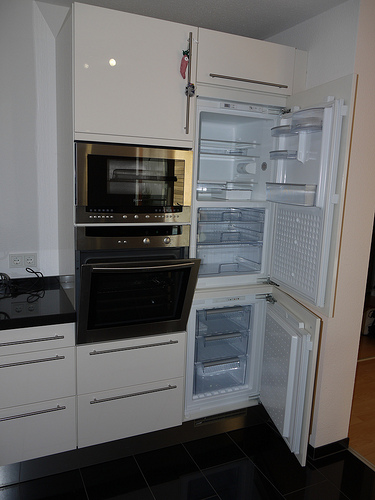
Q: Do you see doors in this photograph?
A: Yes, there is a door.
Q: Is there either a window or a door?
A: Yes, there is a door.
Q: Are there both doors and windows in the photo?
A: No, there is a door but no windows.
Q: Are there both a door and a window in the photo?
A: No, there is a door but no windows.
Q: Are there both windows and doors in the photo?
A: No, there is a door but no windows.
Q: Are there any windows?
A: No, there are no windows.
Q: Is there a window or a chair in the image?
A: No, there are no windows or chairs.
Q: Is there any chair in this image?
A: No, there are no chairs.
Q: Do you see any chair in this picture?
A: No, there are no chairs.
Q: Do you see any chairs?
A: No, there are no chairs.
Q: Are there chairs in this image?
A: No, there are no chairs.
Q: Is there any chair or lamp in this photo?
A: No, there are no chairs or lamps.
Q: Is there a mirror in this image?
A: No, there are no mirrors.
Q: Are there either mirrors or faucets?
A: No, there are no mirrors or faucets.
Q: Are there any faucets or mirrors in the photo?
A: No, there are no mirrors or faucets.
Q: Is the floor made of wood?
A: Yes, the floor is made of wood.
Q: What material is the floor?
A: The floor is made of wood.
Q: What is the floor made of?
A: The floor is made of wood.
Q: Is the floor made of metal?
A: No, the floor is made of wood.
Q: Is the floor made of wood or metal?
A: The floor is made of wood.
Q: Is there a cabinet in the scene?
A: Yes, there is a cabinet.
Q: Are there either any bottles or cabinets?
A: Yes, there is a cabinet.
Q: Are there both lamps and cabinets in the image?
A: No, there is a cabinet but no lamps.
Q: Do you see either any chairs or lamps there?
A: No, there are no chairs or lamps.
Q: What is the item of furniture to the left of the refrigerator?
A: The piece of furniture is a cabinet.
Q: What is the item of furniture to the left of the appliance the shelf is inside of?
A: The piece of furniture is a cabinet.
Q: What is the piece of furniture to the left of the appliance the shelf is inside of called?
A: The piece of furniture is a cabinet.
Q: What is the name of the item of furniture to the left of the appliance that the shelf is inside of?
A: The piece of furniture is a cabinet.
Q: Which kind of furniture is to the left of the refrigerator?
A: The piece of furniture is a cabinet.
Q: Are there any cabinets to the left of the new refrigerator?
A: Yes, there is a cabinet to the left of the refrigerator.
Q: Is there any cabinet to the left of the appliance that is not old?
A: Yes, there is a cabinet to the left of the refrigerator.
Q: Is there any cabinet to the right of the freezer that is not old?
A: No, the cabinet is to the left of the fridge.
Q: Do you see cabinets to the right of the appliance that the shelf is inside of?
A: No, the cabinet is to the left of the fridge.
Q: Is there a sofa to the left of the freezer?
A: No, there is a cabinet to the left of the freezer.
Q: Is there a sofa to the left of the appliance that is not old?
A: No, there is a cabinet to the left of the freezer.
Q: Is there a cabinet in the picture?
A: Yes, there is a cabinet.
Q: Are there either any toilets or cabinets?
A: Yes, there is a cabinet.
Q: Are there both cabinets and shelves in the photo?
A: Yes, there are both a cabinet and a shelf.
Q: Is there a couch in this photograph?
A: No, there are no couches.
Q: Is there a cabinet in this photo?
A: Yes, there is a cabinet.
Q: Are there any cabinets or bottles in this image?
A: Yes, there is a cabinet.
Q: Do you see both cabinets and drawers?
A: Yes, there are both a cabinet and drawers.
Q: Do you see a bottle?
A: No, there are no bottles.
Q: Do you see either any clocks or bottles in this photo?
A: No, there are no bottles or clocks.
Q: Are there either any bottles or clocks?
A: No, there are no bottles or clocks.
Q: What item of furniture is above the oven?
A: The piece of furniture is a cabinet.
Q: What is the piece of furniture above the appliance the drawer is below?
A: The piece of furniture is a cabinet.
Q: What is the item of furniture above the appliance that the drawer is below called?
A: The piece of furniture is a cabinet.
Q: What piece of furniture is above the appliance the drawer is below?
A: The piece of furniture is a cabinet.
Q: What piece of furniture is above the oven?
A: The piece of furniture is a cabinet.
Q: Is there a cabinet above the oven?
A: Yes, there is a cabinet above the oven.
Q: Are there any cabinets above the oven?
A: Yes, there is a cabinet above the oven.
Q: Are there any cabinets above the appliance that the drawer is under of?
A: Yes, there is a cabinet above the oven.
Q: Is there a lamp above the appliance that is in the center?
A: No, there is a cabinet above the oven.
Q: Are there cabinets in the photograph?
A: Yes, there is a cabinet.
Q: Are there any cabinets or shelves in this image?
A: Yes, there is a cabinet.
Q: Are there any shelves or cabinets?
A: Yes, there is a cabinet.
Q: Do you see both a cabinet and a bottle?
A: No, there is a cabinet but no bottles.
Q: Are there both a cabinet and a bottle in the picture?
A: No, there is a cabinet but no bottles.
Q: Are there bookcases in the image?
A: No, there are no bookcases.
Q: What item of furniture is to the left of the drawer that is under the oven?
A: The piece of furniture is a cabinet.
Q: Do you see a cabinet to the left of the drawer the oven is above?
A: Yes, there is a cabinet to the left of the drawer.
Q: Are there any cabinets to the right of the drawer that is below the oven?
A: No, the cabinet is to the left of the drawer.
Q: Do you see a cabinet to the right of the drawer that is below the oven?
A: No, the cabinet is to the left of the drawer.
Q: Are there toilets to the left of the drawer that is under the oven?
A: No, there is a cabinet to the left of the drawer.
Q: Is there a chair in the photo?
A: No, there are no chairs.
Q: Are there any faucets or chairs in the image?
A: No, there are no chairs or faucets.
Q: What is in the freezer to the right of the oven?
A: The drawer is in the freezer.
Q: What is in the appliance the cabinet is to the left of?
A: The drawer is in the freezer.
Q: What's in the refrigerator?
A: The drawer is in the freezer.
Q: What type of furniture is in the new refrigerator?
A: The piece of furniture is a drawer.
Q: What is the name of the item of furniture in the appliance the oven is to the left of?
A: The piece of furniture is a drawer.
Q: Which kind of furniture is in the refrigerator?
A: The piece of furniture is a drawer.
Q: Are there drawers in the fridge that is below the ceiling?
A: Yes, there is a drawer in the refrigerator.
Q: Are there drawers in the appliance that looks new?
A: Yes, there is a drawer in the refrigerator.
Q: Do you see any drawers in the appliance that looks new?
A: Yes, there is a drawer in the refrigerator.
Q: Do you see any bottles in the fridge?
A: No, there is a drawer in the fridge.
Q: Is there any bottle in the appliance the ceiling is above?
A: No, there is a drawer in the fridge.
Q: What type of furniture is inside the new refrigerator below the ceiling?
A: The piece of furniture is a drawer.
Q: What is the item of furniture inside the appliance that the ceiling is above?
A: The piece of furniture is a drawer.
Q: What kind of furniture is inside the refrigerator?
A: The piece of furniture is a drawer.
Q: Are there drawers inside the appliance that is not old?
A: Yes, there is a drawer inside the freezer.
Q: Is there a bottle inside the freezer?
A: No, there is a drawer inside the freezer.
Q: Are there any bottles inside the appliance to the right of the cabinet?
A: No, there is a drawer inside the freezer.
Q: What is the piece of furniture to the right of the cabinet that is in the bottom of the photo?
A: The piece of furniture is a drawer.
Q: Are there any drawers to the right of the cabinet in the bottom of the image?
A: Yes, there is a drawer to the right of the cabinet.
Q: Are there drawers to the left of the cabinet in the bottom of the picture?
A: No, the drawer is to the right of the cabinet.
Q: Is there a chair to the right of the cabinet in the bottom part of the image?
A: No, there is a drawer to the right of the cabinet.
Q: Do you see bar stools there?
A: No, there are no bar stools.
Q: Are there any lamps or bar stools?
A: No, there are no bar stools or lamps.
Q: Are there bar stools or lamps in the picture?
A: No, there are no bar stools or lamps.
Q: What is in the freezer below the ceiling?
A: The drawer is in the freezer.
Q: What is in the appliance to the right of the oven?
A: The drawer is in the freezer.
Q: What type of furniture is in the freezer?
A: The piece of furniture is a drawer.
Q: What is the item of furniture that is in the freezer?
A: The piece of furniture is a drawer.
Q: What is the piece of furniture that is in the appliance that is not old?
A: The piece of furniture is a drawer.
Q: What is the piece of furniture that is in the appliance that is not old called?
A: The piece of furniture is a drawer.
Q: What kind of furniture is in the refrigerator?
A: The piece of furniture is a drawer.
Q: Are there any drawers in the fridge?
A: Yes, there is a drawer in the fridge.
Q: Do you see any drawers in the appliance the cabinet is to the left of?
A: Yes, there is a drawer in the fridge.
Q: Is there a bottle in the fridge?
A: No, there is a drawer in the fridge.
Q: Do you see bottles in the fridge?
A: No, there is a drawer in the fridge.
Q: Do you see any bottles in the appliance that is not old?
A: No, there is a drawer in the fridge.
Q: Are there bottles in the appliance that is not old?
A: No, there is a drawer in the fridge.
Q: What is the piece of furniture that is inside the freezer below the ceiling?
A: The piece of furniture is a drawer.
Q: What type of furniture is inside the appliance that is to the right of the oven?
A: The piece of furniture is a drawer.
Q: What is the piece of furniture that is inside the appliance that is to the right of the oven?
A: The piece of furniture is a drawer.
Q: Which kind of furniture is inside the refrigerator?
A: The piece of furniture is a drawer.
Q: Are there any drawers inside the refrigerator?
A: Yes, there is a drawer inside the refrigerator.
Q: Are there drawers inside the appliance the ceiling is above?
A: Yes, there is a drawer inside the refrigerator.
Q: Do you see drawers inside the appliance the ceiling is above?
A: Yes, there is a drawer inside the refrigerator.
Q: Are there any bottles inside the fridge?
A: No, there is a drawer inside the fridge.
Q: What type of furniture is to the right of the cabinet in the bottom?
A: The piece of furniture is a drawer.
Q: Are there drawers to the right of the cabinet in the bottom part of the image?
A: Yes, there is a drawer to the right of the cabinet.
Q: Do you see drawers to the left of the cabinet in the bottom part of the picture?
A: No, the drawer is to the right of the cabinet.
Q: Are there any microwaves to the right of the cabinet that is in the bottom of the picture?
A: No, there is a drawer to the right of the cabinet.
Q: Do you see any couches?
A: No, there are no couches.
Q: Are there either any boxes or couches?
A: No, there are no couches or boxes.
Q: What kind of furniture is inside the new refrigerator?
A: The piece of furniture is a shelf.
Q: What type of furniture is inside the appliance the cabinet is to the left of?
A: The piece of furniture is a shelf.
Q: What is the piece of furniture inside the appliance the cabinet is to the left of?
A: The piece of furniture is a shelf.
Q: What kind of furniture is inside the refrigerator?
A: The piece of furniture is a shelf.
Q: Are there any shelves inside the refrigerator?
A: Yes, there is a shelf inside the refrigerator.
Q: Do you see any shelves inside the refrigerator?
A: Yes, there is a shelf inside the refrigerator.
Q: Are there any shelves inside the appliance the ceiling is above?
A: Yes, there is a shelf inside the refrigerator.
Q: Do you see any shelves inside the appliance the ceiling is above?
A: Yes, there is a shelf inside the refrigerator.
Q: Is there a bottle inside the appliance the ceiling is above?
A: No, there is a shelf inside the refrigerator.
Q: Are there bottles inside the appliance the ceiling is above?
A: No, there is a shelf inside the refrigerator.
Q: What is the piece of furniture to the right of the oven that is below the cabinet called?
A: The piece of furniture is a shelf.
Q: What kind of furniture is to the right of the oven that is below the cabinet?
A: The piece of furniture is a shelf.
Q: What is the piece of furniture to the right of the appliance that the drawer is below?
A: The piece of furniture is a shelf.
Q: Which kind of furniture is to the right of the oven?
A: The piece of furniture is a shelf.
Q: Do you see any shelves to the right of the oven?
A: Yes, there is a shelf to the right of the oven.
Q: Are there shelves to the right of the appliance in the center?
A: Yes, there is a shelf to the right of the oven.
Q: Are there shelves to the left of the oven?
A: No, the shelf is to the right of the oven.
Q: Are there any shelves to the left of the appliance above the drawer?
A: No, the shelf is to the right of the oven.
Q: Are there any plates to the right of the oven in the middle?
A: No, there is a shelf to the right of the oven.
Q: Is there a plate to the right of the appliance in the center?
A: No, there is a shelf to the right of the oven.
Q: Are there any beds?
A: No, there are no beds.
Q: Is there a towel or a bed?
A: No, there are no beds or towels.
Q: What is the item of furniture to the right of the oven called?
A: The piece of furniture is a shelf.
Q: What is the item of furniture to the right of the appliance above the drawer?
A: The piece of furniture is a shelf.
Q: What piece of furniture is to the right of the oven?
A: The piece of furniture is a shelf.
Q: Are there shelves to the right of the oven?
A: Yes, there is a shelf to the right of the oven.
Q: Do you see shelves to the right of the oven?
A: Yes, there is a shelf to the right of the oven.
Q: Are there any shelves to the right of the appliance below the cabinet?
A: Yes, there is a shelf to the right of the oven.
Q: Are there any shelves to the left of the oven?
A: No, the shelf is to the right of the oven.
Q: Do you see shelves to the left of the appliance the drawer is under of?
A: No, the shelf is to the right of the oven.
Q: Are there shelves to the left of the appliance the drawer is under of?
A: No, the shelf is to the right of the oven.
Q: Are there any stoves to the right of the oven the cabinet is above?
A: No, there is a shelf to the right of the oven.